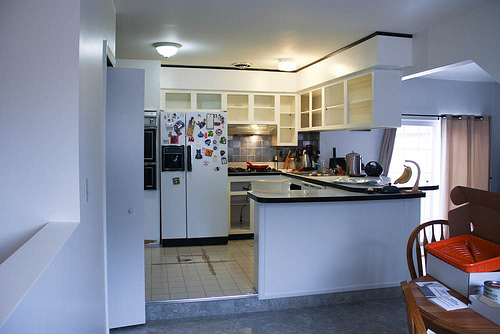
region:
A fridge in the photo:
[166, 128, 222, 236]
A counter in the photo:
[258, 173, 415, 210]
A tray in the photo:
[429, 235, 496, 259]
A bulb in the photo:
[152, 30, 184, 72]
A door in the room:
[120, 103, 137, 223]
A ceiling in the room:
[227, 1, 304, 73]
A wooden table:
[430, 288, 465, 323]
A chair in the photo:
[398, 284, 420, 331]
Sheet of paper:
[425, 269, 461, 315]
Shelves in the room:
[255, 93, 348, 119]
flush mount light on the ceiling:
[148, 38, 188, 60]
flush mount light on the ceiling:
[275, 53, 302, 77]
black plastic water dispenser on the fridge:
[157, 141, 187, 176]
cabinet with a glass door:
[345, 70, 378, 128]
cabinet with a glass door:
[317, 77, 349, 130]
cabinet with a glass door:
[298, 88, 322, 130]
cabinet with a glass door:
[275, 90, 302, 147]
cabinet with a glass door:
[251, 90, 275, 121]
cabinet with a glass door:
[221, 90, 254, 124]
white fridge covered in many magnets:
[158, 108, 226, 250]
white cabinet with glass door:
[344, 70, 379, 131]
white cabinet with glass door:
[320, 78, 347, 130]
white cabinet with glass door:
[298, 85, 324, 130]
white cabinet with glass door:
[275, 93, 298, 148]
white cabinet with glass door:
[251, 94, 275, 123]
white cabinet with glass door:
[225, 93, 253, 123]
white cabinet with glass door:
[191, 93, 223, 112]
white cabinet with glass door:
[159, 90, 197, 110]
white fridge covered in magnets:
[158, 105, 233, 244]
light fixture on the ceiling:
[154, 40, 179, 62]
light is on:
[275, 55, 302, 78]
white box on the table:
[422, 172, 499, 299]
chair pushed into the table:
[388, 268, 487, 333]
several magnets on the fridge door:
[184, 115, 230, 180]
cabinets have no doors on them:
[164, 75, 380, 148]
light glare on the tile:
[246, 135, 260, 147]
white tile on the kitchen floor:
[143, 233, 270, 302]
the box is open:
[423, 184, 498, 298]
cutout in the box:
[467, 220, 475, 230]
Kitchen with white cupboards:
[103, 24, 422, 291]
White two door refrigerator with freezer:
[154, 106, 236, 247]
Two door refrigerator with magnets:
[157, 104, 232, 252]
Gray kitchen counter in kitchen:
[228, 156, 430, 208]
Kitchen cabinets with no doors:
[157, 69, 404, 146]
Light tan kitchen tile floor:
[142, 236, 264, 302]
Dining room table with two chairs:
[395, 213, 497, 333]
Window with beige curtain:
[382, 107, 494, 294]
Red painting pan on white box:
[424, 232, 499, 301]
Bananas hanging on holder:
[388, 157, 425, 199]